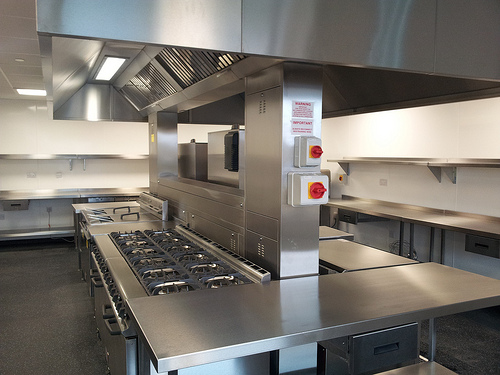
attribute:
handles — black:
[81, 194, 157, 224]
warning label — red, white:
[290, 97, 314, 134]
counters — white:
[0, 150, 147, 201]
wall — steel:
[147, 61, 283, 279]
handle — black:
[101, 301, 116, 321]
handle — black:
[104, 315, 122, 336]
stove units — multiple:
[106, 213, 244, 298]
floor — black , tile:
[7, 250, 73, 372]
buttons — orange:
[298, 139, 328, 194]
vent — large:
[115, 63, 177, 112]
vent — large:
[154, 43, 258, 93]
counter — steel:
[94, 174, 497, 366]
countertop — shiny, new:
[126, 257, 498, 368]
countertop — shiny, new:
[313, 231, 416, 273]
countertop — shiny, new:
[333, 182, 498, 241]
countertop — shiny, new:
[3, 175, 151, 205]